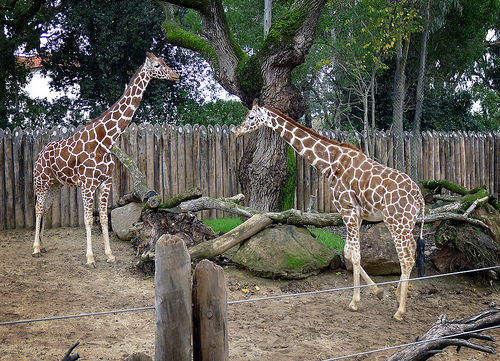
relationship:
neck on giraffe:
[92, 61, 151, 143] [29, 53, 180, 272]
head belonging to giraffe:
[235, 97, 266, 138] [235, 100, 428, 318]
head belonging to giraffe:
[232, 97, 262, 139] [233, 65, 437, 329]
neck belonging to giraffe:
[262, 105, 338, 175] [173, 69, 498, 296]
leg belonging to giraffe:
[32, 181, 111, 256] [13, 48, 185, 266]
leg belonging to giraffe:
[343, 215, 417, 306] [235, 100, 428, 318]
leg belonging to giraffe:
[345, 209, 362, 310] [235, 100, 428, 318]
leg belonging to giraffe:
[32, 181, 111, 256] [29, 53, 180, 272]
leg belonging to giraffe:
[75, 181, 95, 269] [29, 53, 180, 272]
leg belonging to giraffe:
[343, 215, 417, 306] [318, 137, 431, 253]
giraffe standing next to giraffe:
[29, 53, 180, 272] [235, 100, 428, 318]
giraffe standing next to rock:
[235, 100, 428, 318] [225, 213, 337, 275]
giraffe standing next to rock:
[29, 53, 180, 272] [225, 213, 337, 275]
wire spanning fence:
[0, 261, 484, 324] [1, 231, 484, 357]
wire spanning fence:
[320, 324, 480, 359] [1, 231, 484, 357]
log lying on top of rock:
[171, 194, 494, 264] [231, 217, 341, 280]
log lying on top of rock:
[171, 194, 494, 264] [342, 217, 419, 275]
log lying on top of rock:
[171, 194, 494, 264] [428, 218, 498, 284]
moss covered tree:
[202, 28, 320, 99] [158, 0, 336, 226]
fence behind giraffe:
[0, 125, 497, 224] [235, 100, 428, 318]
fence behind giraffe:
[0, 125, 497, 224] [29, 53, 180, 272]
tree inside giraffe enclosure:
[182, 21, 432, 256] [32, 24, 496, 359]